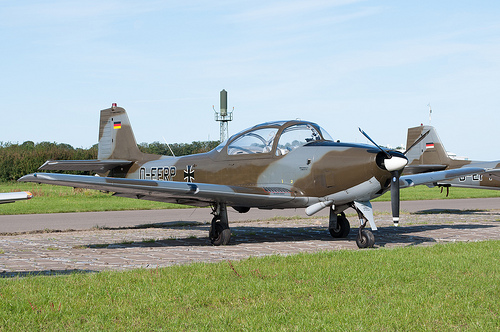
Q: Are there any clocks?
A: No, there are no clocks.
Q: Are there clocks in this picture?
A: No, there are no clocks.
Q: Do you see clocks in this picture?
A: No, there are no clocks.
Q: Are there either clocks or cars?
A: No, there are no clocks or cars.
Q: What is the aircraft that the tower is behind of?
A: The aircraft is a jet.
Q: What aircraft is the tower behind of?
A: The tower is behind the jet.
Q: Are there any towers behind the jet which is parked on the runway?
A: Yes, there is a tower behind the jet.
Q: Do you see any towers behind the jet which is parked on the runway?
A: Yes, there is a tower behind the jet.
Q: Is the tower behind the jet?
A: Yes, the tower is behind the jet.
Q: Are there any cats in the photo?
A: No, there are no cats.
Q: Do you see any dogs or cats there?
A: No, there are no cats or dogs.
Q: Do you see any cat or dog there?
A: No, there are no cats or dogs.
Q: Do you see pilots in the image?
A: No, there are no pilots.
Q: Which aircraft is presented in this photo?
A: The aircraft is a jet.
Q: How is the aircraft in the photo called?
A: The aircraft is a jet.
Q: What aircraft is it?
A: The aircraft is a jet.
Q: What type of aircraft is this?
A: This is a jet.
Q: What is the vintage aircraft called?
A: The aircraft is a jet.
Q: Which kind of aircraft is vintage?
A: The aircraft is a jet.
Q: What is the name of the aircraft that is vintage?
A: The aircraft is a jet.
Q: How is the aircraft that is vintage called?
A: The aircraft is a jet.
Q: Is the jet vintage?
A: Yes, the jet is vintage.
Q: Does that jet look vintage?
A: Yes, the jet is vintage.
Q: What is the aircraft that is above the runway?
A: The aircraft is a jet.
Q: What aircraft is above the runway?
A: The aircraft is a jet.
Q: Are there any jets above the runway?
A: Yes, there is a jet above the runway.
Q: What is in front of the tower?
A: The jet is in front of the tower.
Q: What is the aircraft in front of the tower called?
A: The aircraft is a jet.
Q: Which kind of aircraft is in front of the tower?
A: The aircraft is a jet.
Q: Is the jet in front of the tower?
A: Yes, the jet is in front of the tower.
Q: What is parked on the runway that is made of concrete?
A: The jet is parked on the runway.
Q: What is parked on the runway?
A: The jet is parked on the runway.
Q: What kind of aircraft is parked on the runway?
A: The aircraft is a jet.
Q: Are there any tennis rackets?
A: No, there are no tennis rackets.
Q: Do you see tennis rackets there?
A: No, there are no tennis rackets.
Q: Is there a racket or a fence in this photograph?
A: No, there are no rackets or fences.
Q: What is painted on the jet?
A: The logo is painted on the jet.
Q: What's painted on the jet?
A: The logo is painted on the jet.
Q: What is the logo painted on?
A: The logo is painted on the jet.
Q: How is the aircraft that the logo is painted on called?
A: The aircraft is a jet.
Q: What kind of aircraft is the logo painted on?
A: The logo is painted on the jet.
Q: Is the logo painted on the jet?
A: Yes, the logo is painted on the jet.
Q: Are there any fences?
A: No, there are no fences.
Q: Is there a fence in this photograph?
A: No, there are no fences.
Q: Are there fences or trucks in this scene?
A: No, there are no fences or trucks.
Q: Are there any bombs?
A: No, there are no bombs.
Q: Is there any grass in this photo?
A: Yes, there is grass.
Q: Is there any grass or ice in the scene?
A: Yes, there is grass.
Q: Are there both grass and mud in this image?
A: No, there is grass but no mud.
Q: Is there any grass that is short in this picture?
A: Yes, there is short grass.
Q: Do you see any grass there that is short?
A: Yes, there is grass that is short.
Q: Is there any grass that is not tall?
A: Yes, there is short grass.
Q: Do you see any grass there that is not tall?
A: Yes, there is short grass.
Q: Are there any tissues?
A: No, there are no tissues.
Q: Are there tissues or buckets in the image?
A: No, there are no tissues or buckets.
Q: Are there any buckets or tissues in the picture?
A: No, there are no tissues or buckets.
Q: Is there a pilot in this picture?
A: No, there are no pilots.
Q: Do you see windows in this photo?
A: Yes, there is a window.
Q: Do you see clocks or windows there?
A: Yes, there is a window.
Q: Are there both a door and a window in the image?
A: No, there is a window but no doors.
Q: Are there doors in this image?
A: No, there are no doors.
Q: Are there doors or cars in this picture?
A: No, there are no doors or cars.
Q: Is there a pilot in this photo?
A: No, there are no pilots.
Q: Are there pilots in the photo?
A: No, there are no pilots.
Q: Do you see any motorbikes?
A: No, there are no motorbikes.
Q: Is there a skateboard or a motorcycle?
A: No, there are no motorcycles or skateboards.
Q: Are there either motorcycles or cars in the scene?
A: No, there are no cars or motorcycles.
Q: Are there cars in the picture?
A: No, there are no cars.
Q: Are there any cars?
A: No, there are no cars.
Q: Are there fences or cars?
A: No, there are no cars or fences.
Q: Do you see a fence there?
A: No, there are no fences.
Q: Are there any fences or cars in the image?
A: No, there are no fences or cars.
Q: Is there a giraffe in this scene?
A: No, there are no giraffes.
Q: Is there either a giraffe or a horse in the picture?
A: No, there are no giraffes or horses.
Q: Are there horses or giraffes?
A: No, there are no giraffes or horses.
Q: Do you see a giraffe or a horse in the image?
A: No, there are no giraffes or horses.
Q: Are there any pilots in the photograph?
A: No, there are no pilots.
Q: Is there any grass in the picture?
A: Yes, there is grass.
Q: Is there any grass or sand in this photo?
A: Yes, there is grass.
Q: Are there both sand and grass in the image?
A: No, there is grass but no sand.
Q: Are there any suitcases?
A: No, there are no suitcases.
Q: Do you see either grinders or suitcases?
A: No, there are no suitcases or grinders.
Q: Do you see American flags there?
A: No, there are no American flags.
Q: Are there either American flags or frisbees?
A: No, there are no American flags or frisbees.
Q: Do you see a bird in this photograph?
A: No, there are no birds.